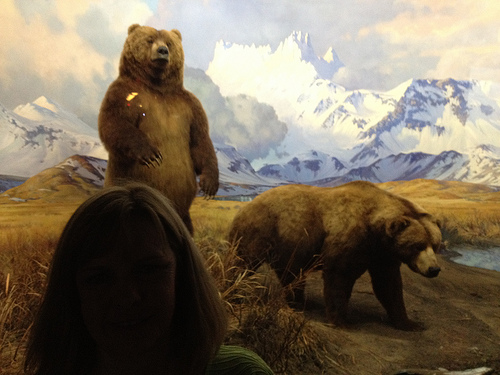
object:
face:
[66, 208, 181, 374]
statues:
[224, 174, 463, 343]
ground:
[447, 178, 500, 375]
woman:
[16, 183, 276, 375]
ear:
[125, 22, 143, 35]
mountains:
[212, 25, 350, 148]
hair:
[19, 181, 230, 375]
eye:
[402, 242, 422, 256]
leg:
[367, 263, 431, 334]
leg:
[319, 267, 361, 330]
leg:
[273, 265, 309, 314]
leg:
[224, 252, 260, 306]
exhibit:
[1, 0, 499, 374]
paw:
[127, 146, 169, 175]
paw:
[197, 170, 221, 203]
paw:
[392, 315, 428, 333]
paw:
[326, 308, 359, 330]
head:
[389, 208, 448, 281]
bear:
[93, 20, 219, 238]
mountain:
[0, 93, 87, 205]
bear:
[221, 177, 453, 334]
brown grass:
[0, 167, 500, 245]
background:
[220, 31, 499, 179]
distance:
[219, 27, 499, 161]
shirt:
[205, 335, 273, 375]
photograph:
[0, 0, 500, 375]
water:
[462, 250, 497, 265]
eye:
[431, 237, 442, 253]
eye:
[164, 36, 170, 46]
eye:
[145, 35, 154, 44]